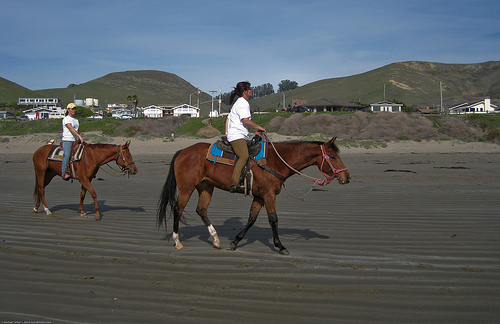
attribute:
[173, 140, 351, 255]
horse — brown, walking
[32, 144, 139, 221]
horse — brown, walking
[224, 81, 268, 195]
woman — riding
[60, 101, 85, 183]
woman — riding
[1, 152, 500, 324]
beach — sandy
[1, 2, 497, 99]
sky — blue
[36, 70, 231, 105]
hill — green, far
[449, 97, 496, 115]
house — white, far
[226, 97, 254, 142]
shirt — white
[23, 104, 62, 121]
house — white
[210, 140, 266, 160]
blanket — blue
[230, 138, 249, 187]
pants — brown